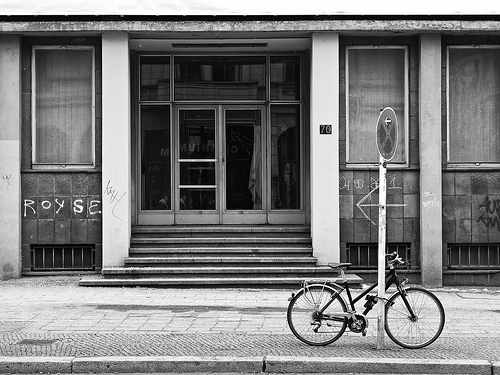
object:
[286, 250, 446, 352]
bike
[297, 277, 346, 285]
cargo rack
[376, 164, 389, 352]
post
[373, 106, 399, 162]
sign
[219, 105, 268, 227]
office door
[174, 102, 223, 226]
office door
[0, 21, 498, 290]
building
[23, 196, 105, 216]
grafitti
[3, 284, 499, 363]
sidewalk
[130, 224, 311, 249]
stairs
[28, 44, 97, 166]
window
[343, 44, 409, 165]
window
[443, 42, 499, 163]
window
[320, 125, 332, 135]
address numerals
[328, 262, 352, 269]
seat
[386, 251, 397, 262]
handlebar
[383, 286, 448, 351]
front wheel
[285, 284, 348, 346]
back wheel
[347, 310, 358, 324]
pedal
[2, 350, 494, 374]
curb